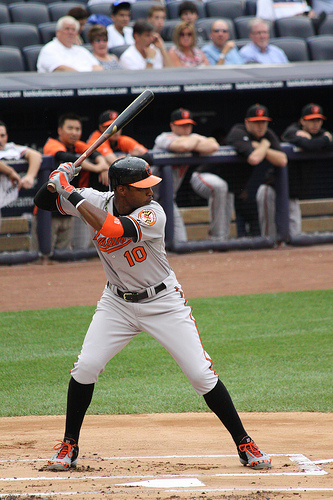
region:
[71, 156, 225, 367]
this is a man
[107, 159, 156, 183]
this is a helmet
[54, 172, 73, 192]
this is a glove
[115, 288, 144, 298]
this is a belt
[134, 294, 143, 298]
the belt is black in color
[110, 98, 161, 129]
this is a bat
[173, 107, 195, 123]
this is a cap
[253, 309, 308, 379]
this is a grass area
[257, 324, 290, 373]
the grass is green in color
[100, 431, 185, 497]
this is the playing ground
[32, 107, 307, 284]
baseball players watching baseball game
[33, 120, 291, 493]
baseball player at bat on field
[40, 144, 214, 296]
baseball player wearing black and orange helmet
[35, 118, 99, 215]
orange and black shirt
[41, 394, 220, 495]
white home plate in batter's box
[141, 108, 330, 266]
players' leaning on black railing by dugout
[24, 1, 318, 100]
people sitting in seats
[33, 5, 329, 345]
people watching baseball game behind dugout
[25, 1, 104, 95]
man sitting wearing white shirt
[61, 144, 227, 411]
white baseball pants with orange stripe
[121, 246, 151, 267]
Bright orange number ten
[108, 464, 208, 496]
White baseball plate on the ground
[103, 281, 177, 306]
Dark belt with metal buckle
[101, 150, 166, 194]
Black and orange helmet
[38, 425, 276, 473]
Gray and orange baseball shoes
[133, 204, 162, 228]
Baseball team logo on sleeve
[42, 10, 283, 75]
Audience watching from the stands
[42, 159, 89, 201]
Gray and orange batting gloves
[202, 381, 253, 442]
Long black sock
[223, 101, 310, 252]
Team member watching in the background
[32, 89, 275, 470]
baseball player swinging bat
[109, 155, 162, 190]
black batter's helmet with orange bill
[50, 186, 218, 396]
white and orange baseball uniform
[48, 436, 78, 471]
black and white athletic shoes with orange laces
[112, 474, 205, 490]
home plate on baseball field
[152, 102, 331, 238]
players watching batter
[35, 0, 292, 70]
spectators in stands watching batter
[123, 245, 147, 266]
orange number on white uniform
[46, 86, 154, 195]
bat held back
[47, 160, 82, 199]
baseball gloves on batter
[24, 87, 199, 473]
a batter up to plate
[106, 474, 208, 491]
A white home plate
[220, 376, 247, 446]
black socks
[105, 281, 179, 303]
a black belt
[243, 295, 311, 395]
green grass on the field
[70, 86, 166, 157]
wooden baseball bat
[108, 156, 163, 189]
a black and orange hat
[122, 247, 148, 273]
number 10 on unform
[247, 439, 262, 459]
orange on a shoe string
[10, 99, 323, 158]
team players watching